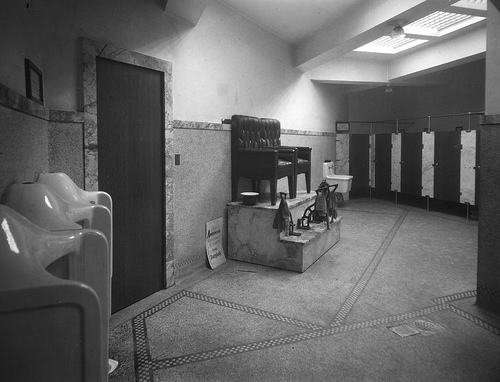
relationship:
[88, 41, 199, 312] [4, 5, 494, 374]
door in bathroom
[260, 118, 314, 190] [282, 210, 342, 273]
cushioned seat atop of step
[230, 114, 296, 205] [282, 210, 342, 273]
cushioned seat atop of step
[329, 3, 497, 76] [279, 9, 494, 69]
lights on ceiling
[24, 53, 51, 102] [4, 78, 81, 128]
frame on ledge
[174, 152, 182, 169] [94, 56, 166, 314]
light switch on right side door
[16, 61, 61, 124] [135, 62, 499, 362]
certificate for washroom.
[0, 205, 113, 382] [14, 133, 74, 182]
urinals on wall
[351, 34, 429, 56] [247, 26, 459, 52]
lights in ceiling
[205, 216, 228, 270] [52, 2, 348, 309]
flyer against wall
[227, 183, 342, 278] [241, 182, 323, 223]
stand on step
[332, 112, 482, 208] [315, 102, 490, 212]
bathroom stalls are in row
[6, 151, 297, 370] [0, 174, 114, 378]
urinals are in row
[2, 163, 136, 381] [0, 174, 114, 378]
urinals are in row